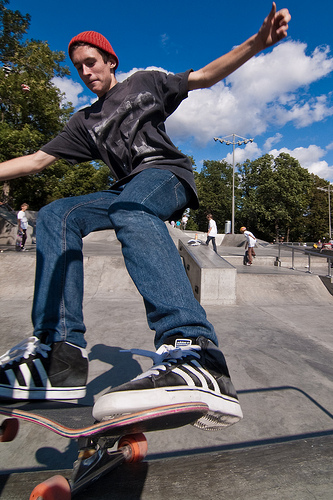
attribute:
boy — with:
[230, 223, 267, 278]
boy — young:
[7, 21, 313, 463]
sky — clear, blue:
[22, 3, 332, 75]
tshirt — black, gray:
[47, 61, 204, 199]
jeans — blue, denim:
[29, 174, 223, 353]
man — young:
[5, 7, 298, 490]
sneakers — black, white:
[5, 321, 247, 430]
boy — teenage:
[0, 2, 291, 431]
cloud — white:
[158, 33, 179, 54]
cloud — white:
[165, 40, 332, 143]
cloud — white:
[260, 132, 282, 150]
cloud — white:
[222, 141, 261, 165]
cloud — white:
[264, 144, 332, 181]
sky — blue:
[1, 0, 332, 186]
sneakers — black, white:
[1, 321, 256, 443]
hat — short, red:
[67, 30, 118, 71]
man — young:
[0, 3, 294, 433]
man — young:
[239, 224, 257, 265]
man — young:
[202, 212, 219, 251]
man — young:
[16, 199, 29, 253]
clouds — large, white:
[41, 40, 331, 147]